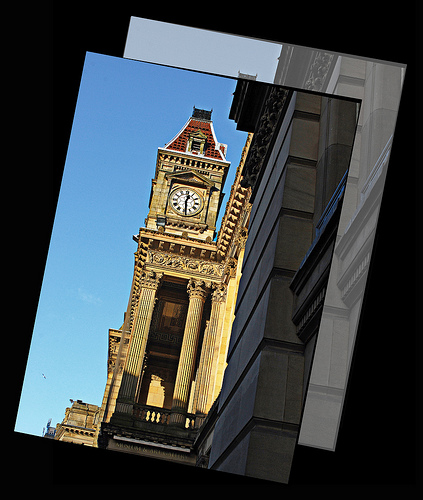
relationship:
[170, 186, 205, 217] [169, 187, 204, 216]
clock on clock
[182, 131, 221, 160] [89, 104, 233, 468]
window on clock tower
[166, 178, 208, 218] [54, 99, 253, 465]
clock on building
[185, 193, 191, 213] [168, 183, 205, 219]
hand on clock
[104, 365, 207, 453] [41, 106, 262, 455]
shadow on building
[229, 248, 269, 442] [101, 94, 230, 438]
wall in front of tower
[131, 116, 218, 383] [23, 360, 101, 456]
building in distance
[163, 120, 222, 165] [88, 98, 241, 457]
roof of building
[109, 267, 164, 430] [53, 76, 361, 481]
column supporting building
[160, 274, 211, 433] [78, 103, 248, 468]
column supporting building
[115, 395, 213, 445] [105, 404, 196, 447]
railing at edge of porch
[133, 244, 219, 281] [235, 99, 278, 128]
sidework under eaves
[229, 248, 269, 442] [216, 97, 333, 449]
wall made of stone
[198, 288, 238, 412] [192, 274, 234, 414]
light on surface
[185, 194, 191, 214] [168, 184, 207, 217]
hand on clock